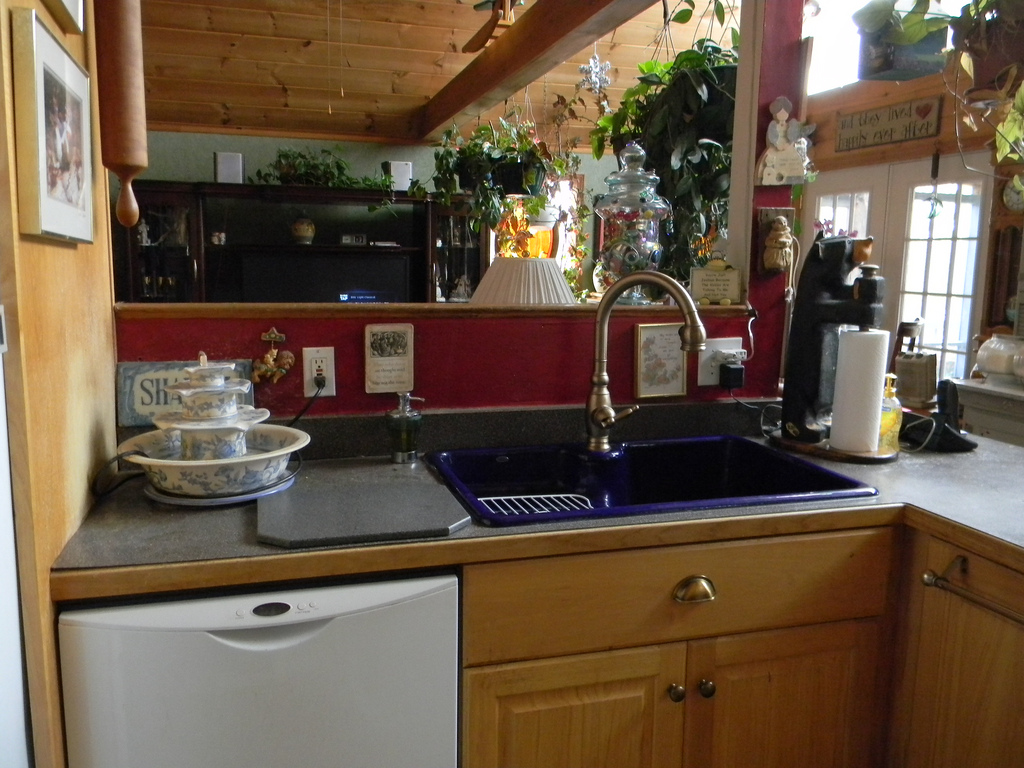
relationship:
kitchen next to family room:
[7, 2, 1023, 750] [99, 1, 1020, 304]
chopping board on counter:
[267, 451, 471, 546] [84, 500, 674, 561]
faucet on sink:
[584, 271, 707, 455] [429, 422, 875, 549]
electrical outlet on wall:
[302, 347, 337, 398] [120, 307, 756, 407]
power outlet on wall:
[696, 334, 741, 391] [447, 307, 778, 396]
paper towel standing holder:
[829, 328, 890, 451] [814, 306, 887, 452]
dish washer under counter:
[57, 574, 459, 768] [66, 530, 553, 576]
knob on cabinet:
[697, 672, 726, 699] [697, 612, 890, 765]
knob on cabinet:
[666, 682, 690, 699] [463, 637, 695, 765]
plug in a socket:
[311, 372, 328, 393] [304, 341, 339, 409]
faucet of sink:
[589, 271, 703, 452] [447, 427, 884, 546]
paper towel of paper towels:
[829, 328, 890, 451] [822, 313, 898, 466]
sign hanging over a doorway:
[801, 96, 951, 167] [785, 142, 1001, 381]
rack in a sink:
[471, 477, 601, 531] [418, 406, 891, 537]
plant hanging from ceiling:
[472, 80, 549, 211] [140, 0, 1010, 177]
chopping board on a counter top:
[257, 453, 472, 549] [62, 383, 1021, 562]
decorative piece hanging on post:
[760, 97, 814, 189] [718, 3, 814, 310]